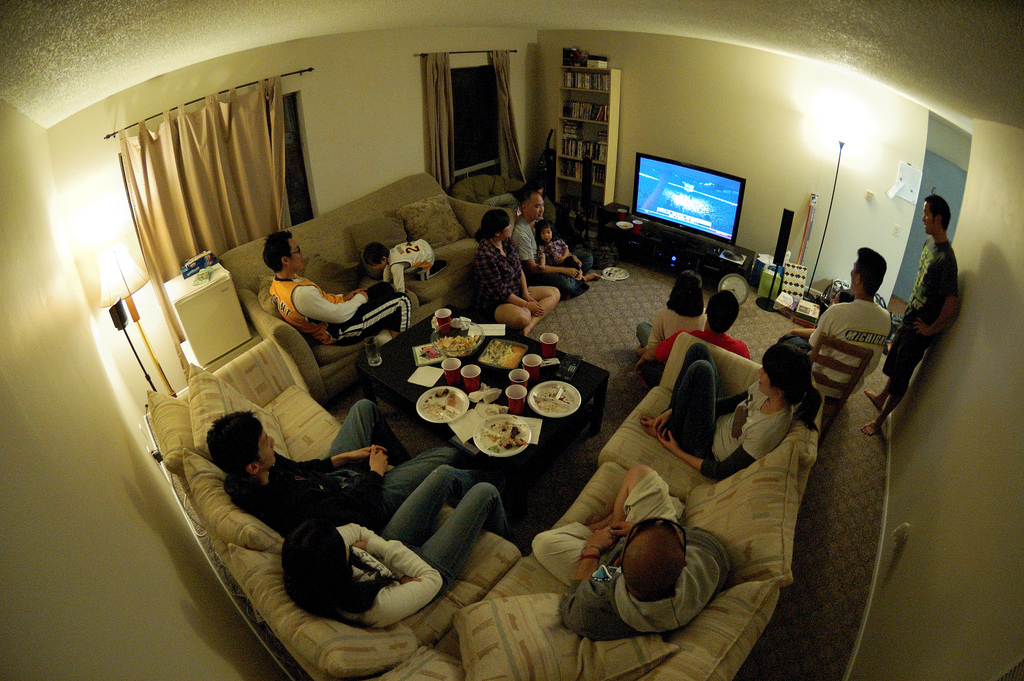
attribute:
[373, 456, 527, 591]
pants — blue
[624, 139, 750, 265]
television — on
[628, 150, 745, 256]
screen — lcd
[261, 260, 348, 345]
jersey — yellow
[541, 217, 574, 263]
girl — YOUNG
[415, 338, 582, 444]
cups — PLASTIC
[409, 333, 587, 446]
plates — DISPOSABLE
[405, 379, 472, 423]
plate — dining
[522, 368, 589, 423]
plate — dining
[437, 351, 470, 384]
vessel — drinking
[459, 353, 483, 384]
vessel — drinking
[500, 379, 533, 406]
vessel — drinking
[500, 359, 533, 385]
vessel — drinking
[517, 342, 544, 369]
vessel — drinking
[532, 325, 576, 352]
vessel — drinking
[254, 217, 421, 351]
person — sitting, down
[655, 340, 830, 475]
person — down, sitting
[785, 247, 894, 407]
person — sitting, down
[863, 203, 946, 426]
person — down, sitting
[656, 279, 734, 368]
person — sitting, down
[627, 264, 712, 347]
person — down, sitting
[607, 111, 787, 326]
tv — large, plasma